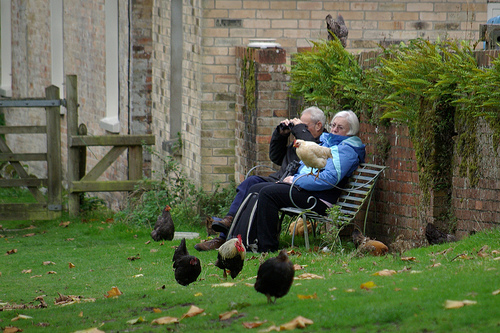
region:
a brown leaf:
[443, 295, 475, 307]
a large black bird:
[172, 250, 206, 290]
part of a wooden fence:
[1, 83, 71, 209]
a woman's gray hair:
[331, 110, 358, 134]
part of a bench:
[282, 162, 388, 255]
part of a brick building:
[195, 0, 490, 47]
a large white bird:
[289, 137, 332, 176]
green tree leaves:
[362, 38, 497, 122]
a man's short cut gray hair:
[300, 105, 324, 127]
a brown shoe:
[196, 235, 227, 253]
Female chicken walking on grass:
[250, 247, 301, 305]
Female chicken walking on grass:
[213, 230, 253, 282]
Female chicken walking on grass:
[167, 240, 206, 292]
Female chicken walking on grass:
[150, 203, 182, 240]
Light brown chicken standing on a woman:
[290, 135, 333, 174]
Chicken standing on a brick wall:
[321, 10, 356, 47]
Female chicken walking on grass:
[287, 213, 322, 239]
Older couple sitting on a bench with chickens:
[232, 106, 366, 258]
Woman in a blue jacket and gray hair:
[267, 106, 372, 249]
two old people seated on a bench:
[197, 100, 359, 250]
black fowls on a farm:
[150, 202, 294, 305]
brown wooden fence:
[0, 62, 154, 228]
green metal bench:
[281, 159, 384, 248]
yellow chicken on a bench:
[291, 138, 331, 178]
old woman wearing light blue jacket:
[250, 110, 365, 247]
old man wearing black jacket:
[194, 105, 328, 250]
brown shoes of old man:
[195, 215, 232, 251]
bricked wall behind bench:
[239, 41, 496, 245]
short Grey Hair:
[327, 109, 359, 138]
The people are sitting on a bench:
[30, 27, 478, 302]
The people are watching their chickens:
[16, 47, 467, 330]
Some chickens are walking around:
[41, 33, 464, 320]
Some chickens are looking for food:
[25, 32, 475, 327]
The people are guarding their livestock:
[5, 17, 471, 329]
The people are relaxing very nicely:
[13, 37, 474, 318]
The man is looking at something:
[30, 35, 466, 315]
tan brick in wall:
[419, 8, 446, 24]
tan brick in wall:
[357, 7, 394, 24]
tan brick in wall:
[334, 8, 363, 27]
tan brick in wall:
[293, 14, 324, 32]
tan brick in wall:
[267, 18, 297, 33]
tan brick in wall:
[239, 14, 272, 31]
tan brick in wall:
[200, 20, 234, 45]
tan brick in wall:
[200, 63, 225, 75]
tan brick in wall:
[203, 155, 226, 164]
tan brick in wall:
[406, 3, 433, 11]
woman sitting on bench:
[222, 108, 367, 253]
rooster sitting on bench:
[289, 134, 331, 177]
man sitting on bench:
[174, 103, 332, 251]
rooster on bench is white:
[291, 132, 334, 175]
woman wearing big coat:
[283, 128, 368, 202]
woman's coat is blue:
[280, 127, 365, 209]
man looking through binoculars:
[276, 114, 306, 139]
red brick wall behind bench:
[287, 61, 494, 250]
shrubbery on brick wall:
[279, 25, 499, 176]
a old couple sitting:
[142, 99, 410, 306]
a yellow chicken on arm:
[285, 120, 332, 191]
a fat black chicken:
[240, 245, 317, 307]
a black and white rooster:
[216, 228, 243, 285]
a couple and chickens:
[138, 97, 374, 309]